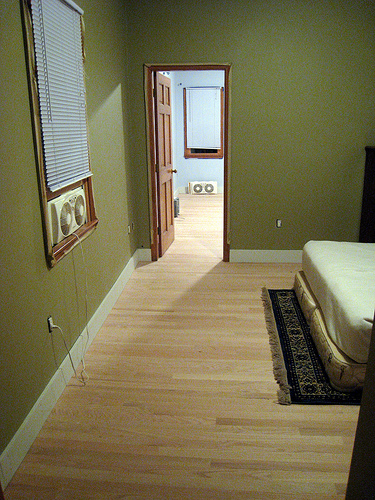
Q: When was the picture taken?
A: At night.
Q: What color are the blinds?
A: White.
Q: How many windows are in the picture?
A: Two.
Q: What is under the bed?
A: A rug.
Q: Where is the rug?
A: Under the bed.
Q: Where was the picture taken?
A: In a bedroom.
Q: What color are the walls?
A: Green.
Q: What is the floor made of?
A: Wood.